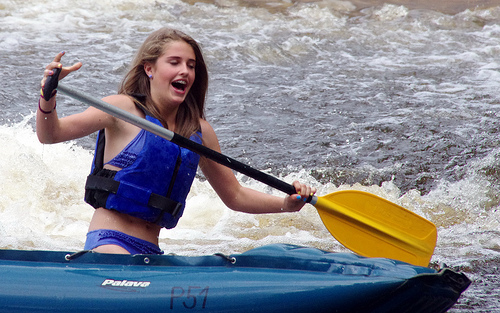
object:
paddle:
[40, 66, 440, 268]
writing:
[163, 285, 213, 311]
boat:
[0, 239, 475, 311]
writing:
[101, 277, 153, 288]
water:
[0, 1, 500, 312]